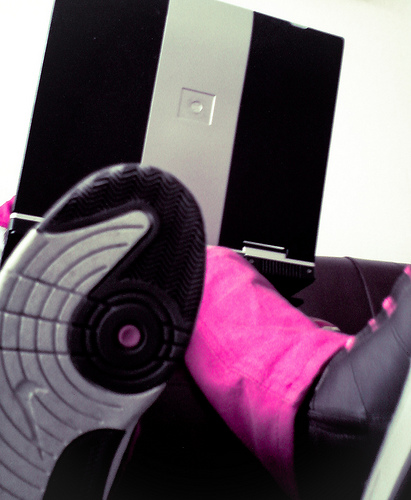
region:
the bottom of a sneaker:
[15, 158, 175, 495]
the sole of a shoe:
[3, 162, 224, 496]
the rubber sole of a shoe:
[0, 145, 215, 497]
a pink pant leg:
[182, 229, 340, 463]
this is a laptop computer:
[26, 0, 350, 273]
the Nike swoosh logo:
[1, 364, 79, 498]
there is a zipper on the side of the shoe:
[299, 391, 383, 469]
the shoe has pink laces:
[332, 253, 403, 379]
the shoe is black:
[285, 245, 406, 498]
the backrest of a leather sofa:
[320, 248, 409, 343]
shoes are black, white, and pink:
[0, 161, 409, 498]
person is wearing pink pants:
[180, 245, 361, 498]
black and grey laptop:
[8, 1, 342, 300]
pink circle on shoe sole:
[117, 323, 141, 349]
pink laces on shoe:
[340, 260, 410, 350]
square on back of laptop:
[176, 84, 216, 126]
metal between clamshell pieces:
[7, 211, 318, 272]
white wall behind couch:
[1, 0, 410, 264]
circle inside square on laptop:
[189, 100, 202, 114]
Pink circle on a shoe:
[118, 324, 141, 348]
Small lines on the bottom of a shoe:
[70, 226, 149, 253]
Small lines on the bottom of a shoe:
[35, 230, 100, 292]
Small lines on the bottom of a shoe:
[35, 273, 74, 331]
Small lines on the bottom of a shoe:
[3, 283, 67, 345]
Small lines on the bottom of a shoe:
[36, 335, 112, 409]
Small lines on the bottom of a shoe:
[1, 346, 78, 397]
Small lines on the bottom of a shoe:
[0, 390, 103, 438]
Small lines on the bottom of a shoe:
[0, 435, 82, 481]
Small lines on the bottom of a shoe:
[2, 467, 57, 499]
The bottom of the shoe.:
[10, 183, 187, 498]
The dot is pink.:
[113, 321, 143, 349]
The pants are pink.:
[188, 246, 325, 458]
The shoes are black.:
[302, 263, 409, 497]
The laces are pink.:
[340, 267, 406, 348]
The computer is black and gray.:
[10, 19, 355, 282]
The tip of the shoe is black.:
[72, 163, 201, 258]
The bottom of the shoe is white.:
[6, 160, 162, 491]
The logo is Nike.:
[4, 372, 56, 459]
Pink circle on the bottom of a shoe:
[115, 322, 143, 347]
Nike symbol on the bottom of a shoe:
[13, 374, 56, 456]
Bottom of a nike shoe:
[0, 149, 209, 498]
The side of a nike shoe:
[295, 252, 409, 498]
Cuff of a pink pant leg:
[205, 240, 348, 466]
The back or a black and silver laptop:
[18, 0, 346, 272]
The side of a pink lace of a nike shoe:
[343, 332, 357, 347]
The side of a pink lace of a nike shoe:
[365, 317, 376, 331]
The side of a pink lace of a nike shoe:
[381, 293, 399, 318]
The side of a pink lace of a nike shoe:
[400, 258, 409, 279]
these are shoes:
[42, 176, 342, 486]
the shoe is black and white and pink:
[65, 190, 205, 418]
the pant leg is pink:
[200, 269, 345, 426]